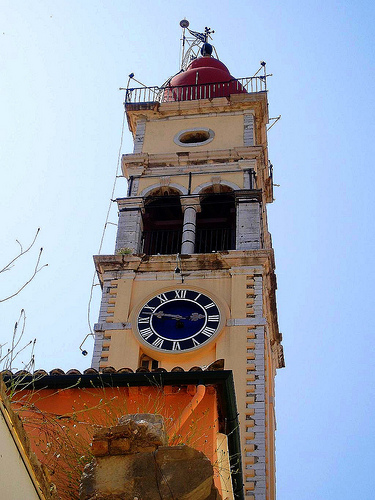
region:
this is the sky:
[271, 11, 323, 43]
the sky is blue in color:
[297, 380, 324, 412]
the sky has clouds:
[306, 404, 330, 458]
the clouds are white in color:
[314, 416, 351, 454]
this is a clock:
[134, 283, 232, 352]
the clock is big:
[125, 282, 249, 359]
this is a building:
[87, 9, 287, 492]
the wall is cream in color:
[237, 284, 247, 303]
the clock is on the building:
[134, 280, 224, 355]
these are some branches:
[15, 371, 96, 435]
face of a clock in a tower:
[105, 268, 259, 368]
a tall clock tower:
[110, 20, 288, 447]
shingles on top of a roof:
[9, 361, 217, 384]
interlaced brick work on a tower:
[242, 271, 268, 491]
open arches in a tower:
[137, 177, 248, 247]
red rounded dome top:
[163, 53, 240, 95]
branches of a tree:
[6, 338, 84, 469]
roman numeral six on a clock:
[168, 339, 182, 351]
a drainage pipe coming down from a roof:
[166, 385, 206, 445]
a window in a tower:
[164, 117, 221, 148]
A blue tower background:
[304, 392, 365, 428]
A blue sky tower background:
[287, 323, 374, 443]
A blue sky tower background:
[285, 250, 354, 327]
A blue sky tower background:
[299, 110, 370, 265]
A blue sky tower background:
[285, 29, 373, 94]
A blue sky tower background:
[4, 100, 117, 219]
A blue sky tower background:
[22, 29, 120, 89]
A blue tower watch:
[137, 273, 216, 357]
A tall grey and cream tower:
[113, 60, 283, 495]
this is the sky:
[89, 54, 112, 65]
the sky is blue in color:
[318, 359, 340, 400]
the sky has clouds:
[291, 395, 339, 440]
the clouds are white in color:
[297, 457, 345, 487]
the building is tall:
[102, 1, 286, 494]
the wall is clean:
[127, 284, 145, 295]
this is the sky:
[285, 6, 343, 213]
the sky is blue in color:
[295, 21, 363, 162]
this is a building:
[120, 108, 296, 374]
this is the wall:
[140, 121, 230, 163]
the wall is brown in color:
[146, 122, 169, 150]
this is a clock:
[130, 286, 222, 343]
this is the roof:
[88, 368, 227, 393]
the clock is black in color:
[165, 316, 186, 337]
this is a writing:
[157, 334, 182, 355]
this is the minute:
[154, 306, 181, 322]